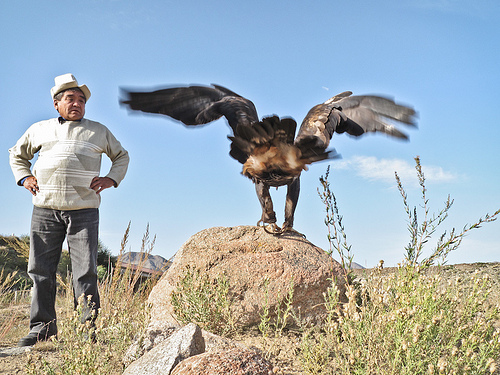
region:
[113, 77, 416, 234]
bird about to take flight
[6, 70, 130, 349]
man standing and watching bird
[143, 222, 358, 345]
giant rock under bird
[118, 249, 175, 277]
tall mountain in background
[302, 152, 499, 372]
grass and plants next to rock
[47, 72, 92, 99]
beige hat on man's head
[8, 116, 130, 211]
white sweater with lines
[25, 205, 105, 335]
dark grey jeans on man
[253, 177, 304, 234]
legs of bird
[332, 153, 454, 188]
small white cloud in sky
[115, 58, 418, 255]
a large bird on a rock.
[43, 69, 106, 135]
an old man wearing a hat.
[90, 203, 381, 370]
a large rock on a desert floor.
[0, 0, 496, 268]
a clear blue sky.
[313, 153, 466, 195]
a white cloud in a clear sky.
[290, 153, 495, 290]
a plant on a desert.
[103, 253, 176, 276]
a mountain in a background.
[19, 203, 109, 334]
a pair of gray pants.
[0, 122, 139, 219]
a white t shirt.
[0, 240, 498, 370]
a field with plant life.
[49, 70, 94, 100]
The hat the man is wearing.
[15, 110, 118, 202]
The sweater the man is wearing.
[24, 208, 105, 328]
The gray pants the man is wearing.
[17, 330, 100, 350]
The black shoes the man is wearing.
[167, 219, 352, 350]
The rock the bird is on.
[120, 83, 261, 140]
The left wing of the bird.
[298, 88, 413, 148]
The right wing of the bird.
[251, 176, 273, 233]
The left leg of the bird.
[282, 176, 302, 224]
The right leg of the bird.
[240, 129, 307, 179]
The body of the bird.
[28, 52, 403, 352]
a man and a bird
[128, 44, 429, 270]
this bird is barely recognizable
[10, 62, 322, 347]
the man is observing the bird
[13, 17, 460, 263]
the sky is clear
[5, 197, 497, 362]
this scene is taking place in the desert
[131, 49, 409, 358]
this bird is perched on a large rock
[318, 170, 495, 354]
desert shrubbery in the picture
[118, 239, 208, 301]
a rocky area in the background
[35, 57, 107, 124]
the man is wearing a hat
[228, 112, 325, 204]
this bird's face cannot be seen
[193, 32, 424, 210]
bird on the rock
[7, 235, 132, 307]
pants on the man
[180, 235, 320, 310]
rock under the bird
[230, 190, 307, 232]
legs of the bird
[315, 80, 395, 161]
wing of the bird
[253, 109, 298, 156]
tail feather of the bird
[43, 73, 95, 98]
hat on the man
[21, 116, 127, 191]
shirt on the man's back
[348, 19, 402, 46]
blue sky above the bird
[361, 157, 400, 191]
cloud in the sky